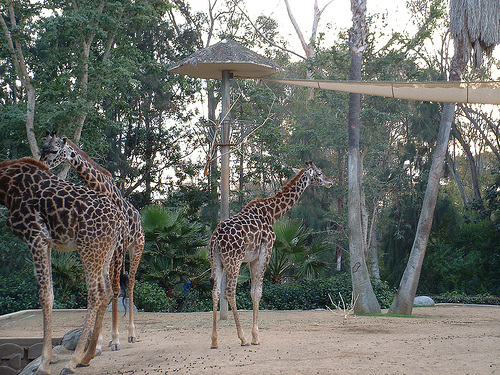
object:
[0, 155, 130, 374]
giraffes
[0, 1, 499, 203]
sky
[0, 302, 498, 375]
ground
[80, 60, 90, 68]
leaves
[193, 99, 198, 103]
leaves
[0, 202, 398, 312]
bushes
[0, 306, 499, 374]
dirt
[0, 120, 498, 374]
enclosure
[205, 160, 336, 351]
giraffe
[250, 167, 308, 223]
neck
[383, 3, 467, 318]
trees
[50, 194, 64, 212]
spots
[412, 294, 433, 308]
rock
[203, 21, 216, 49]
branch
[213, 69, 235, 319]
beam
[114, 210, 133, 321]
tail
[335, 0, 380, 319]
tree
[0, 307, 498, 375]
sand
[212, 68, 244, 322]
pole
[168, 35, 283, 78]
lid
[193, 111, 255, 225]
basket